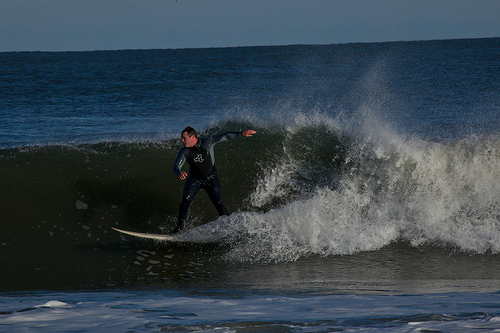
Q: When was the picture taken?
A: During the day.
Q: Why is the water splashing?
A: The waves are crashing.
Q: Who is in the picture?
A: A surfer.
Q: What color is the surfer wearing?
A: Black.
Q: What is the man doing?
A: Surfing.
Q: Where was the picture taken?
A: At the beach.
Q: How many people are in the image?
A: One.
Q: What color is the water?
A: Blue.